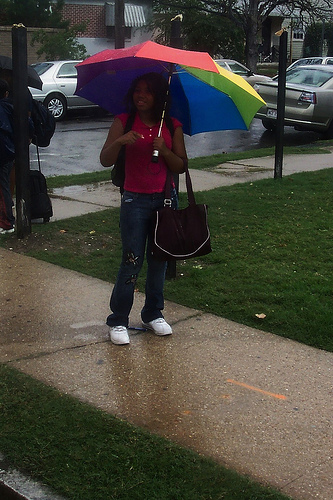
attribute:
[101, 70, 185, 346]
girl — holding, white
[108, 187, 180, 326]
pants — blue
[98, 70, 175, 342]
girl — wearing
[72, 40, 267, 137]
umbrella — colorful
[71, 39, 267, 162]
umbrella — colorful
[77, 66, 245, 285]
girl — holding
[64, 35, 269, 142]
umbrella — rainbow striped